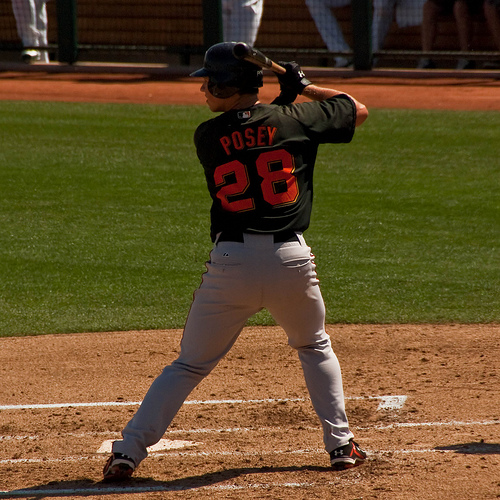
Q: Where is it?
A: This is at the field.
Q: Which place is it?
A: It is a field.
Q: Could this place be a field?
A: Yes, it is a field.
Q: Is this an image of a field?
A: Yes, it is showing a field.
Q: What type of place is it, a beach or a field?
A: It is a field.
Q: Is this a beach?
A: No, it is a field.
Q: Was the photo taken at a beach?
A: No, the picture was taken in a field.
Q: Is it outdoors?
A: Yes, it is outdoors.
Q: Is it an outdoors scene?
A: Yes, it is outdoors.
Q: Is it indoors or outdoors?
A: It is outdoors.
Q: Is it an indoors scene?
A: No, it is outdoors.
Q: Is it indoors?
A: No, it is outdoors.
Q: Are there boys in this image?
A: No, there are no boys.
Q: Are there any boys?
A: No, there are no boys.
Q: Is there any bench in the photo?
A: No, there are no benches.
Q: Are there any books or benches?
A: No, there are no benches or books.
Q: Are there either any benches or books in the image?
A: No, there are no benches or books.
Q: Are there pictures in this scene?
A: No, there are no pictures.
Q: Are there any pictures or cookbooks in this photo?
A: No, there are no pictures or cookbooks.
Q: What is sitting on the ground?
A: The home plate is sitting on the ground.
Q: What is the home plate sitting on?
A: The home plate is sitting on the ground.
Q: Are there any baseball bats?
A: Yes, there is a baseball bat.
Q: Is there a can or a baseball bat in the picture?
A: Yes, there is a baseball bat.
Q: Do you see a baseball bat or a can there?
A: Yes, there is a baseball bat.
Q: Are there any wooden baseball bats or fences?
A: Yes, there is a wood baseball bat.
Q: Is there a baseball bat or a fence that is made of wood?
A: Yes, the baseball bat is made of wood.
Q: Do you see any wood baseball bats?
A: Yes, there is a wood baseball bat.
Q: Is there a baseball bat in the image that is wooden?
A: Yes, there is a baseball bat that is wooden.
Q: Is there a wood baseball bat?
A: Yes, there is a baseball bat that is made of wood.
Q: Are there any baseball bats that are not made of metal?
A: Yes, there is a baseball bat that is made of wood.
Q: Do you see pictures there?
A: No, there are no pictures.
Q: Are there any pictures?
A: No, there are no pictures.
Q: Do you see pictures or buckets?
A: No, there are no pictures or buckets.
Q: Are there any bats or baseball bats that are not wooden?
A: No, there is a baseball bat but it is wooden.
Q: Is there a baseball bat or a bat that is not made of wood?
A: No, there is a baseball bat but it is made of wood.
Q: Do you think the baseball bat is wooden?
A: Yes, the baseball bat is wooden.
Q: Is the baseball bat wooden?
A: Yes, the baseball bat is wooden.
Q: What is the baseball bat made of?
A: The baseball bat is made of wood.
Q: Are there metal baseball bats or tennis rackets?
A: No, there is a baseball bat but it is wooden.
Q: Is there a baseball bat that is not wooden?
A: No, there is a baseball bat but it is wooden.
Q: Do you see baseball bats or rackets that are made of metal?
A: No, there is a baseball bat but it is made of wood.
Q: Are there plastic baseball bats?
A: No, there is a baseball bat but it is made of wood.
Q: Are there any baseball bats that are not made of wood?
A: No, there is a baseball bat but it is made of wood.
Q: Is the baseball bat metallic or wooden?
A: The baseball bat is wooden.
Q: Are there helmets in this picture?
A: Yes, there is a helmet.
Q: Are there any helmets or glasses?
A: Yes, there is a helmet.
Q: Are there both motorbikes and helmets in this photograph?
A: No, there is a helmet but no motorcycles.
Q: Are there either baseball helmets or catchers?
A: Yes, there is a baseball helmet.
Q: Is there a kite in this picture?
A: No, there are no kites.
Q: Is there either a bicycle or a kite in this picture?
A: No, there are no kites or bicycles.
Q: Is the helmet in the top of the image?
A: Yes, the helmet is in the top of the image.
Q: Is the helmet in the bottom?
A: No, the helmet is in the top of the image.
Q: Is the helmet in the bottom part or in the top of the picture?
A: The helmet is in the top of the image.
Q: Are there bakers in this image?
A: No, there are no bakers.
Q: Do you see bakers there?
A: No, there are no bakers.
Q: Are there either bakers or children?
A: No, there are no bakers or children.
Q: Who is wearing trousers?
A: The player is wearing trousers.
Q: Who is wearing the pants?
A: The player is wearing trousers.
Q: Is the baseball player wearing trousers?
A: Yes, the player is wearing trousers.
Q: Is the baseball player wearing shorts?
A: No, the player is wearing trousers.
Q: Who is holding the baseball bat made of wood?
A: The player is holding the baseball bat.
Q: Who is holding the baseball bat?
A: The player is holding the baseball bat.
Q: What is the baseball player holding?
A: The player is holding the baseball bat.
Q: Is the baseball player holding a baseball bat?
A: Yes, the player is holding a baseball bat.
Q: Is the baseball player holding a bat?
A: No, the player is holding a baseball bat.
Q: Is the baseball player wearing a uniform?
A: No, the player is wearing a glove.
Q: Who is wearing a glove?
A: The player is wearing a glove.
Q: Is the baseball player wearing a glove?
A: Yes, the player is wearing a glove.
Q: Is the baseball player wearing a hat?
A: No, the player is wearing a glove.